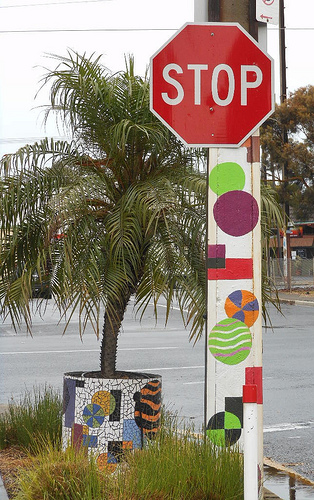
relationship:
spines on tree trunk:
[113, 294, 126, 308] [72, 314, 145, 391]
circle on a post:
[202, 0, 270, 496] [203, 2, 267, 464]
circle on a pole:
[209, 409, 241, 445] [205, 0, 265, 497]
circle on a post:
[207, 317, 253, 367] [196, 338, 269, 497]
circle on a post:
[223, 288, 261, 326] [245, 129, 264, 498]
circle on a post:
[210, 187, 261, 239] [199, 0, 272, 497]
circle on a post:
[213, 189, 260, 237] [203, 133, 264, 498]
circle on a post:
[207, 317, 253, 367] [60, 361, 169, 487]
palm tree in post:
[7, 56, 195, 457] [60, 366, 163, 487]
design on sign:
[80, 401, 104, 429] [144, 21, 281, 152]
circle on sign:
[213, 189, 260, 237] [146, 11, 277, 157]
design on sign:
[95, 451, 117, 474] [146, 11, 277, 157]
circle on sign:
[206, 409, 242, 447] [145, 1, 277, 498]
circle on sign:
[207, 317, 253, 367] [149, 21, 277, 473]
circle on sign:
[224, 289, 259, 329] [144, 21, 281, 152]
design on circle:
[202, 248, 263, 287] [209, 161, 246, 198]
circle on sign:
[209, 161, 246, 198] [146, 11, 277, 157]